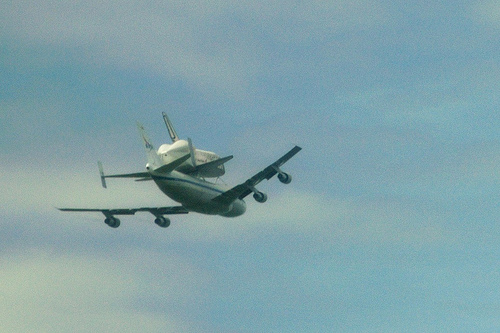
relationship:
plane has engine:
[48, 123, 311, 242] [97, 213, 125, 233]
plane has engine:
[48, 123, 311, 242] [154, 213, 172, 232]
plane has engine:
[48, 123, 311, 242] [250, 186, 268, 205]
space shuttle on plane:
[158, 103, 233, 177] [48, 123, 311, 242]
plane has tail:
[48, 123, 311, 242] [128, 118, 162, 165]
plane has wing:
[48, 123, 311, 242] [211, 144, 306, 194]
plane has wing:
[48, 123, 311, 242] [57, 197, 186, 225]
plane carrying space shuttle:
[48, 123, 311, 242] [158, 103, 233, 177]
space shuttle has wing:
[158, 103, 233, 177] [194, 153, 239, 171]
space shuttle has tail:
[158, 103, 233, 177] [159, 108, 181, 143]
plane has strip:
[48, 123, 311, 242] [153, 170, 223, 195]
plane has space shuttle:
[48, 123, 311, 242] [158, 103, 233, 177]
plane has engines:
[48, 123, 311, 242] [101, 212, 178, 232]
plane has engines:
[48, 123, 311, 242] [250, 166, 298, 203]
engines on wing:
[101, 212, 178, 232] [57, 197, 186, 225]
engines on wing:
[250, 166, 298, 203] [211, 144, 306, 194]